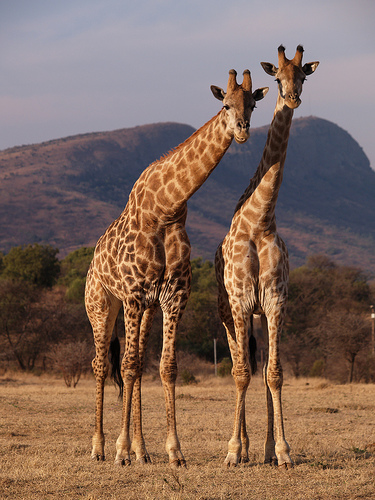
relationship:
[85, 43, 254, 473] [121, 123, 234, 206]
giraffe has neck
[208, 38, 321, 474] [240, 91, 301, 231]
giraffe has neck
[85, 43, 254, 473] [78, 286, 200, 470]
giraffe has legs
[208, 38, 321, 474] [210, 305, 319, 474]
giraffe has legs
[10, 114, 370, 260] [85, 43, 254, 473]
hill behind giraffe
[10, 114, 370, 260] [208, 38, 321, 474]
hill behind giraffe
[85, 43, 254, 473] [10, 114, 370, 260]
giraffe beside hill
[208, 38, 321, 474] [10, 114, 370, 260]
giraffe beside hill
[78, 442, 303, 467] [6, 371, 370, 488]
hooves in grass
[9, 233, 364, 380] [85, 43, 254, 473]
trees behind giraffe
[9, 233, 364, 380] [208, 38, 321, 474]
trees behind giraffe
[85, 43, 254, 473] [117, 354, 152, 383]
giraffe has joint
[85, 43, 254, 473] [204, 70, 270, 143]
giraffe has head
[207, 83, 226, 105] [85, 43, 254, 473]
ear of giraffe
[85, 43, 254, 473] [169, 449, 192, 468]
giraffe has hoof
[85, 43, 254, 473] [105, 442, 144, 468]
giraffe has hoof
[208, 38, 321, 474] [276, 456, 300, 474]
giraffe has hoof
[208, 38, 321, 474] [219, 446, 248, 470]
giraffe has hoof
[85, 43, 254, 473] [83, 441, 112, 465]
giraffe has hoof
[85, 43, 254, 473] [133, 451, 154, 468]
giraffe has hoof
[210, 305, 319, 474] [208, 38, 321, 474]
legs of giraffe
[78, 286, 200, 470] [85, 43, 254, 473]
legs of giraffe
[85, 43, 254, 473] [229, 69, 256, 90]
giraffe has horns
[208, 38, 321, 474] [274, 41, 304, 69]
giraffe has horns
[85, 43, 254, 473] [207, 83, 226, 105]
giraffe has ear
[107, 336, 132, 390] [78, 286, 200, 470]
tail between legs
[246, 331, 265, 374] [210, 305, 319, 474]
tail between legs